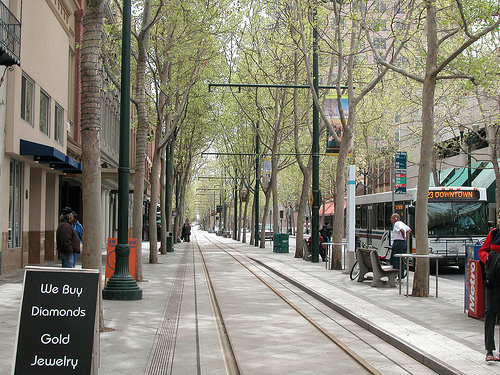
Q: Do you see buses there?
A: Yes, there is a bus.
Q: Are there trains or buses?
A: Yes, there is a bus.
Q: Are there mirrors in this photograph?
A: No, there are no mirrors.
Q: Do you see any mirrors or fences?
A: No, there are no mirrors or fences.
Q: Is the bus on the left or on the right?
A: The bus is on the right of the image.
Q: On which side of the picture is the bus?
A: The bus is on the right of the image.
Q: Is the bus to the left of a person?
A: Yes, the bus is to the left of a person.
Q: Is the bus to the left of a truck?
A: No, the bus is to the left of a person.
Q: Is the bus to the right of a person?
A: No, the bus is to the left of a person.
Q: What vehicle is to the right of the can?
A: The vehicle is a bus.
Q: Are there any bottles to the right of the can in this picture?
A: No, there is a bus to the right of the can.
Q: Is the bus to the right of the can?
A: Yes, the bus is to the right of the can.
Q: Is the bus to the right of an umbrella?
A: No, the bus is to the right of the can.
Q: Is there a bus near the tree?
A: Yes, there is a bus near the tree.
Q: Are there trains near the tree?
A: No, there is a bus near the tree.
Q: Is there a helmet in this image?
A: No, there are no helmets.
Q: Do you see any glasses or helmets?
A: No, there are no helmets or glasses.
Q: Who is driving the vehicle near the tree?
A: The man is driving the bus.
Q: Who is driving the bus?
A: The man is driving the bus.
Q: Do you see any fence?
A: No, there are no fences.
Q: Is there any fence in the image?
A: No, there are no fences.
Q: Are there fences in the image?
A: No, there are no fences.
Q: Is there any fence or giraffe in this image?
A: No, there are no fences or giraffes.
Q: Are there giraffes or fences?
A: No, there are no fences or giraffes.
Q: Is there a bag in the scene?
A: No, there are no bags.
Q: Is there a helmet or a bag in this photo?
A: No, there are no bags or helmets.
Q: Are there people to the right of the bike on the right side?
A: Yes, there is a person to the right of the bike.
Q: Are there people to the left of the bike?
A: No, the person is to the right of the bike.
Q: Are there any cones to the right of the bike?
A: No, there is a person to the right of the bike.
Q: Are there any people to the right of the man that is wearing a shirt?
A: Yes, there is a person to the right of the man.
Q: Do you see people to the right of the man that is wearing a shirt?
A: Yes, there is a person to the right of the man.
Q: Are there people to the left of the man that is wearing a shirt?
A: No, the person is to the right of the man.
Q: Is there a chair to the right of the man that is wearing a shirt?
A: No, there is a person to the right of the man.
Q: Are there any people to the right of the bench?
A: Yes, there is a person to the right of the bench.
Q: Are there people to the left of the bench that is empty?
A: No, the person is to the right of the bench.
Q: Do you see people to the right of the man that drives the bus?
A: Yes, there is a person to the right of the man.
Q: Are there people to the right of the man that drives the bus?
A: Yes, there is a person to the right of the man.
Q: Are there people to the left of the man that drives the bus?
A: No, the person is to the right of the man.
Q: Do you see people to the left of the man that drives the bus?
A: No, the person is to the right of the man.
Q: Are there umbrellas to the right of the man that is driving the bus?
A: No, there is a person to the right of the man.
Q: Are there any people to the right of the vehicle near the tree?
A: Yes, there is a person to the right of the bus.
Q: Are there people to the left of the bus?
A: No, the person is to the right of the bus.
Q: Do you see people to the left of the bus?
A: No, the person is to the right of the bus.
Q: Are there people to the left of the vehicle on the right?
A: No, the person is to the right of the bus.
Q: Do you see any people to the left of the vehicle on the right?
A: No, the person is to the right of the bus.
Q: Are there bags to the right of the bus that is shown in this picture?
A: No, there is a person to the right of the bus.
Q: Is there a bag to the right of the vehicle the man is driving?
A: No, there is a person to the right of the bus.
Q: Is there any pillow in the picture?
A: No, there are no pillows.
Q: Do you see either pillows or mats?
A: No, there are no pillows or mats.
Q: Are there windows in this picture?
A: Yes, there is a window.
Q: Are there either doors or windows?
A: Yes, there is a window.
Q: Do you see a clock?
A: No, there are no clocks.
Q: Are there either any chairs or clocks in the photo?
A: No, there are no clocks or chairs.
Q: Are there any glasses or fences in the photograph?
A: No, there are no fences or glasses.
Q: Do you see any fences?
A: No, there are no fences.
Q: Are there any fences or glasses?
A: No, there are no fences or glasses.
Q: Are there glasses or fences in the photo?
A: No, there are no fences or glasses.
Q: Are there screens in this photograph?
A: No, there are no screens.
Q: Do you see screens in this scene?
A: No, there are no screens.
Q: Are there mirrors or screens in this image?
A: No, there are no screens or mirrors.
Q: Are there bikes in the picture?
A: Yes, there is a bike.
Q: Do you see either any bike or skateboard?
A: Yes, there is a bike.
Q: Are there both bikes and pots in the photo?
A: No, there is a bike but no pots.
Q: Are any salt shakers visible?
A: No, there are no salt shakers.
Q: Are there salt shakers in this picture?
A: No, there are no salt shakers.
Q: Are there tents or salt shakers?
A: No, there are no salt shakers or tents.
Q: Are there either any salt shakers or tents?
A: No, there are no salt shakers or tents.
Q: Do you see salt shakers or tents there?
A: No, there are no salt shakers or tents.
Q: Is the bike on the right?
A: Yes, the bike is on the right of the image.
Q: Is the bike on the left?
A: No, the bike is on the right of the image.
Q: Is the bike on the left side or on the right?
A: The bike is on the right of the image.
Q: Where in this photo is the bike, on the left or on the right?
A: The bike is on the right of the image.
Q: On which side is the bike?
A: The bike is on the right of the image.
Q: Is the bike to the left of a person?
A: Yes, the bike is to the left of a person.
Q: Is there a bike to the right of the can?
A: Yes, there is a bike to the right of the can.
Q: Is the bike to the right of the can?
A: Yes, the bike is to the right of the can.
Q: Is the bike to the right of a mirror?
A: No, the bike is to the right of the can.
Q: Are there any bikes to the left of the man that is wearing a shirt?
A: Yes, there is a bike to the left of the man.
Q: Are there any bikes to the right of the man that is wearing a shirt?
A: No, the bike is to the left of the man.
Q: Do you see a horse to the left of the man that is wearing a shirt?
A: No, there is a bike to the left of the man.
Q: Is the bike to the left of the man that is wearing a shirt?
A: Yes, the bike is to the left of the man.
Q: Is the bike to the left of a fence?
A: No, the bike is to the left of the man.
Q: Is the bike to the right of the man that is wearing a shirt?
A: No, the bike is to the left of the man.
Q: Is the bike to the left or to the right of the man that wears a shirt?
A: The bike is to the left of the man.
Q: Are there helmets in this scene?
A: No, there are no helmets.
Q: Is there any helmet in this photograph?
A: No, there are no helmets.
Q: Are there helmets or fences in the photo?
A: No, there are no helmets or fences.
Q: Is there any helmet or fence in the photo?
A: No, there are no helmets or fences.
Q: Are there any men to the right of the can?
A: Yes, there is a man to the right of the can.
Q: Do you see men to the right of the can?
A: Yes, there is a man to the right of the can.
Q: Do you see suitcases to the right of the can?
A: No, there is a man to the right of the can.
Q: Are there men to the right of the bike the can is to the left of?
A: Yes, there is a man to the right of the bike.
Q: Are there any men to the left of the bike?
A: No, the man is to the right of the bike.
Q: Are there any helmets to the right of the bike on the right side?
A: No, there is a man to the right of the bike.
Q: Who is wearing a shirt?
A: The man is wearing a shirt.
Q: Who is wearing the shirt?
A: The man is wearing a shirt.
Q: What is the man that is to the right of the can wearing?
A: The man is wearing a shirt.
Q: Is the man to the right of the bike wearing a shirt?
A: Yes, the man is wearing a shirt.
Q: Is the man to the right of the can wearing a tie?
A: No, the man is wearing a shirt.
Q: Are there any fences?
A: No, there are no fences.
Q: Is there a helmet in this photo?
A: No, there are no helmets.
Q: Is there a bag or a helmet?
A: No, there are no helmets or bags.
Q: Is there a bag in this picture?
A: No, there are no bags.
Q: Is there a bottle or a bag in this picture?
A: No, there are no bags or bottles.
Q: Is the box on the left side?
A: No, the box is on the right of the image.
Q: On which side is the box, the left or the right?
A: The box is on the right of the image.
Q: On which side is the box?
A: The box is on the right of the image.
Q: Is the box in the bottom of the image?
A: Yes, the box is in the bottom of the image.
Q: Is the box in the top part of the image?
A: No, the box is in the bottom of the image.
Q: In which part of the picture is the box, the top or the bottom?
A: The box is in the bottom of the image.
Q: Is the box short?
A: Yes, the box is short.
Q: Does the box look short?
A: Yes, the box is short.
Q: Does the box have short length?
A: Yes, the box is short.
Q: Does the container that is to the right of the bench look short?
A: Yes, the box is short.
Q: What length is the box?
A: The box is short.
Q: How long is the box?
A: The box is short.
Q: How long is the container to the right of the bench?
A: The box is short.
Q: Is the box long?
A: No, the box is short.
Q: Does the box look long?
A: No, the box is short.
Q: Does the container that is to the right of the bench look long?
A: No, the box is short.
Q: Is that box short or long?
A: The box is short.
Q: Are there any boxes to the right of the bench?
A: Yes, there is a box to the right of the bench.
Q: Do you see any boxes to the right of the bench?
A: Yes, there is a box to the right of the bench.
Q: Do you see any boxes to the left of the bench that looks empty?
A: No, the box is to the right of the bench.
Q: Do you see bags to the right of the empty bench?
A: No, there is a box to the right of the bench.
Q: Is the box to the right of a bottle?
A: No, the box is to the right of a bench.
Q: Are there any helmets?
A: No, there are no helmets.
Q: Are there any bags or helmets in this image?
A: No, there are no helmets or bags.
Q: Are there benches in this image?
A: Yes, there is a bench.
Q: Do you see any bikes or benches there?
A: Yes, there is a bench.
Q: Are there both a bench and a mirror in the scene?
A: No, there is a bench but no mirrors.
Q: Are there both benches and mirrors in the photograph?
A: No, there is a bench but no mirrors.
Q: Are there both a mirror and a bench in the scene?
A: No, there is a bench but no mirrors.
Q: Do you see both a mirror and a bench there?
A: No, there is a bench but no mirrors.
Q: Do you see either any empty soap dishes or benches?
A: Yes, there is an empty bench.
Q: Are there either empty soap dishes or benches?
A: Yes, there is an empty bench.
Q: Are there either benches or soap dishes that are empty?
A: Yes, the bench is empty.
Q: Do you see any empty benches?
A: Yes, there is an empty bench.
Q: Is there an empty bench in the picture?
A: Yes, there is an empty bench.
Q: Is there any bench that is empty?
A: Yes, there is a bench that is empty.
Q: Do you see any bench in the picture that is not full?
A: Yes, there is a empty bench.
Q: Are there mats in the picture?
A: No, there are no mats.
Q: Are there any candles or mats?
A: No, there are no mats or candles.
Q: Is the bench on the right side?
A: Yes, the bench is on the right of the image.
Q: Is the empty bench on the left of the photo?
A: No, the bench is on the right of the image.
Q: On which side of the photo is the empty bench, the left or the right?
A: The bench is on the right of the image.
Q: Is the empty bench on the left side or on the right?
A: The bench is on the right of the image.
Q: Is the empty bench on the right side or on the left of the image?
A: The bench is on the right of the image.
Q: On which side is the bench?
A: The bench is on the right of the image.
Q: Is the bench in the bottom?
A: Yes, the bench is in the bottom of the image.